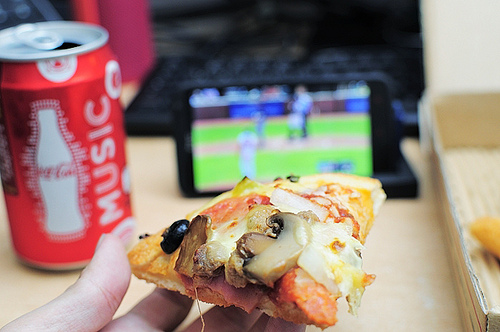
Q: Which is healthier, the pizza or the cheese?
A: The cheese is healthier than the pizza.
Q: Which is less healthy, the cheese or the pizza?
A: The pizza is less healthy than the cheese.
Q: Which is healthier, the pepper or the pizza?
A: The pepper is healthier than the pizza.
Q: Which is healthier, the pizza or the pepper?
A: The pepper is healthier than the pizza.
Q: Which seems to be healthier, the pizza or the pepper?
A: The pepper is healthier than the pizza.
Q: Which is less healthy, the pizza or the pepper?
A: The pizza is less healthy than the pepper.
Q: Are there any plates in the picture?
A: Yes, there is a plate.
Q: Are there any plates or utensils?
A: Yes, there is a plate.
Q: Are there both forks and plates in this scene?
A: No, there is a plate but no forks.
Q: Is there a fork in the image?
A: No, there are no forks.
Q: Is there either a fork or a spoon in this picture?
A: No, there are no forks or spoons.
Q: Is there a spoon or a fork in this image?
A: No, there are no forks or spoons.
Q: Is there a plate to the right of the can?
A: Yes, there is a plate to the right of the can.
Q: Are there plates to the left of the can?
A: No, the plate is to the right of the can.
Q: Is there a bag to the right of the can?
A: No, there is a plate to the right of the can.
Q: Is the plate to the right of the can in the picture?
A: Yes, the plate is to the right of the can.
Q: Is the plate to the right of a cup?
A: No, the plate is to the right of the can.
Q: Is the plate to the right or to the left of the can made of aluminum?
A: The plate is to the right of the can.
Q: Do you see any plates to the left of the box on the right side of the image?
A: Yes, there is a plate to the left of the box.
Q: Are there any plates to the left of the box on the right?
A: Yes, there is a plate to the left of the box.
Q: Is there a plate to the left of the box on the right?
A: Yes, there is a plate to the left of the box.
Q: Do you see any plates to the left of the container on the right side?
A: Yes, there is a plate to the left of the box.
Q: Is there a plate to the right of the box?
A: No, the plate is to the left of the box.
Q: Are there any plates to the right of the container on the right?
A: No, the plate is to the left of the box.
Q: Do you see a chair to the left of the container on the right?
A: No, there is a plate to the left of the box.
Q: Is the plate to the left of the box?
A: Yes, the plate is to the left of the box.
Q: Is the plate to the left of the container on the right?
A: Yes, the plate is to the left of the box.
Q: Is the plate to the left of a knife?
A: No, the plate is to the left of the box.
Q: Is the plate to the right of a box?
A: No, the plate is to the left of a box.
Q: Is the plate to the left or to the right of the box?
A: The plate is to the left of the box.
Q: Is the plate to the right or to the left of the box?
A: The plate is to the left of the box.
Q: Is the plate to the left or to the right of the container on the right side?
A: The plate is to the left of the box.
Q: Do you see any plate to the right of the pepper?
A: Yes, there is a plate to the right of the pepper.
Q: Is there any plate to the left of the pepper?
A: No, the plate is to the right of the pepper.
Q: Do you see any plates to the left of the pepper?
A: No, the plate is to the right of the pepper.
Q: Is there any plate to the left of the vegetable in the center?
A: No, the plate is to the right of the pepper.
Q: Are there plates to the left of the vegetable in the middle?
A: No, the plate is to the right of the pepper.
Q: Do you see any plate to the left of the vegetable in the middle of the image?
A: No, the plate is to the right of the pepper.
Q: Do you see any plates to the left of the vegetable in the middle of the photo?
A: No, the plate is to the right of the pepper.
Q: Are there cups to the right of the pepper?
A: No, there is a plate to the right of the pepper.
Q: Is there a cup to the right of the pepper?
A: No, there is a plate to the right of the pepper.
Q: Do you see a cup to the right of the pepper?
A: No, there is a plate to the right of the pepper.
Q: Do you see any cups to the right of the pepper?
A: No, there is a plate to the right of the pepper.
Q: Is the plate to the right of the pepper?
A: Yes, the plate is to the right of the pepper.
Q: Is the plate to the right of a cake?
A: No, the plate is to the right of the pepper.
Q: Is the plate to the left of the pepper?
A: No, the plate is to the right of the pepper.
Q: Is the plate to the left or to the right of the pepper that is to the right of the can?
A: The plate is to the right of the pepper.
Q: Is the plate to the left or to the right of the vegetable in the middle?
A: The plate is to the right of the pepper.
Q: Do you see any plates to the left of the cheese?
A: Yes, there is a plate to the left of the cheese.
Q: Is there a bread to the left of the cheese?
A: No, there is a plate to the left of the cheese.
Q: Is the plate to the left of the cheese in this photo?
A: Yes, the plate is to the left of the cheese.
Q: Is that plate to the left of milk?
A: No, the plate is to the left of the cheese.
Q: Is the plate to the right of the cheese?
A: No, the plate is to the left of the cheese.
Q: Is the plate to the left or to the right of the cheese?
A: The plate is to the left of the cheese.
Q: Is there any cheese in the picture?
A: Yes, there is cheese.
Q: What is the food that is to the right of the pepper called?
A: The food is cheese.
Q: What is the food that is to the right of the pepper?
A: The food is cheese.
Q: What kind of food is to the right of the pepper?
A: The food is cheese.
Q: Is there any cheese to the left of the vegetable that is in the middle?
A: No, the cheese is to the right of the pepper.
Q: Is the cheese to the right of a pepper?
A: Yes, the cheese is to the right of a pepper.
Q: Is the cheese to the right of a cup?
A: No, the cheese is to the right of a pepper.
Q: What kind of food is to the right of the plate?
A: The food is cheese.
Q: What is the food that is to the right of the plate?
A: The food is cheese.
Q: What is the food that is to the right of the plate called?
A: The food is cheese.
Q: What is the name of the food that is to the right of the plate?
A: The food is cheese.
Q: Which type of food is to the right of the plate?
A: The food is cheese.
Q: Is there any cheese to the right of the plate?
A: Yes, there is cheese to the right of the plate.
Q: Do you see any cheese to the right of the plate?
A: Yes, there is cheese to the right of the plate.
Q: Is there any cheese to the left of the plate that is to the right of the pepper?
A: No, the cheese is to the right of the plate.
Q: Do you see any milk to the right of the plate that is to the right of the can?
A: No, there is cheese to the right of the plate.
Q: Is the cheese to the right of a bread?
A: No, the cheese is to the right of the plate.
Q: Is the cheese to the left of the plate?
A: No, the cheese is to the right of the plate.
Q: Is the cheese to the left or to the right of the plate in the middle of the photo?
A: The cheese is to the right of the plate.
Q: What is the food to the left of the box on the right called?
A: The food is cheese.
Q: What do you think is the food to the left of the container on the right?
A: The food is cheese.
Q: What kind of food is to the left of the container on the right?
A: The food is cheese.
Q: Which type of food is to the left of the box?
A: The food is cheese.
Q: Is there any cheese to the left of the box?
A: Yes, there is cheese to the left of the box.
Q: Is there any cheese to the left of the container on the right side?
A: Yes, there is cheese to the left of the box.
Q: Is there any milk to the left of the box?
A: No, there is cheese to the left of the box.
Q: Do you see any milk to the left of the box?
A: No, there is cheese to the left of the box.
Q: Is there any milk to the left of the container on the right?
A: No, there is cheese to the left of the box.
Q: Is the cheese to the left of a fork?
A: No, the cheese is to the left of a box.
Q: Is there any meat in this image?
A: Yes, there is meat.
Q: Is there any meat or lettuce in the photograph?
A: Yes, there is meat.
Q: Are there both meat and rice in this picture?
A: No, there is meat but no rice.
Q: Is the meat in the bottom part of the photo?
A: Yes, the meat is in the bottom of the image.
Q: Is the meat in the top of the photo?
A: No, the meat is in the bottom of the image.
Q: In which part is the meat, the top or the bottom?
A: The meat is in the bottom of the image.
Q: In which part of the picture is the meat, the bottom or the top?
A: The meat is in the bottom of the image.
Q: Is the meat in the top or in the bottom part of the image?
A: The meat is in the bottom of the image.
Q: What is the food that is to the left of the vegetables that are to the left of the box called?
A: The food is meat.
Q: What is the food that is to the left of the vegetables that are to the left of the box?
A: The food is meat.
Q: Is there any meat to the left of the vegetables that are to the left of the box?
A: Yes, there is meat to the left of the veggies.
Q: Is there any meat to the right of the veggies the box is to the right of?
A: No, the meat is to the left of the vegetables.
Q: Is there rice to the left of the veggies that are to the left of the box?
A: No, there is meat to the left of the veggies.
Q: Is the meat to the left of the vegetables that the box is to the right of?
A: Yes, the meat is to the left of the veggies.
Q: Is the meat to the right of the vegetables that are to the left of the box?
A: No, the meat is to the left of the vegetables.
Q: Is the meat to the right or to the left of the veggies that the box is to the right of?
A: The meat is to the left of the vegetables.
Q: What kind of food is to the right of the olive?
A: The food is meat.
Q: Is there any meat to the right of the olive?
A: Yes, there is meat to the right of the olive.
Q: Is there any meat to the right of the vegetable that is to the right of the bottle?
A: Yes, there is meat to the right of the olive.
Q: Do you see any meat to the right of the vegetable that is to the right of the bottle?
A: Yes, there is meat to the right of the olive.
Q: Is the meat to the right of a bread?
A: No, the meat is to the right of the olive.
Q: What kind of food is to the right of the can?
A: The food is meat.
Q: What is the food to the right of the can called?
A: The food is meat.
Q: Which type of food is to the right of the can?
A: The food is meat.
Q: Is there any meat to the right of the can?
A: Yes, there is meat to the right of the can.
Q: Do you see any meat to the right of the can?
A: Yes, there is meat to the right of the can.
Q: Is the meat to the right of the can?
A: Yes, the meat is to the right of the can.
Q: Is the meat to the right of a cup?
A: No, the meat is to the right of the can.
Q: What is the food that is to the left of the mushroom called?
A: The food is meat.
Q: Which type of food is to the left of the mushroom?
A: The food is meat.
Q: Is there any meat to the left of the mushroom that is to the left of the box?
A: Yes, there is meat to the left of the mushroom.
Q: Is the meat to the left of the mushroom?
A: Yes, the meat is to the left of the mushroom.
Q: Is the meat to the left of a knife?
A: No, the meat is to the left of the mushroom.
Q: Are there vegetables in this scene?
A: Yes, there are vegetables.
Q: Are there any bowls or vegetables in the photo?
A: Yes, there are vegetables.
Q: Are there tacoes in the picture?
A: No, there are no tacoes.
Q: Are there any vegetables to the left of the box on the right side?
A: Yes, there are vegetables to the left of the box.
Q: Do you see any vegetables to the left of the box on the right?
A: Yes, there are vegetables to the left of the box.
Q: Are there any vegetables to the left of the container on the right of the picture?
A: Yes, there are vegetables to the left of the box.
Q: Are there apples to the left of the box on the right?
A: No, there are vegetables to the left of the box.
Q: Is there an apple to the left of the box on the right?
A: No, there are vegetables to the left of the box.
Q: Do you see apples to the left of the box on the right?
A: No, there are vegetables to the left of the box.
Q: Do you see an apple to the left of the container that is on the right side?
A: No, there are vegetables to the left of the box.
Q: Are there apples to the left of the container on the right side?
A: No, there are vegetables to the left of the box.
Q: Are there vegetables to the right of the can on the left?
A: Yes, there are vegetables to the right of the can.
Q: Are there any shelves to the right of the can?
A: No, there are vegetables to the right of the can.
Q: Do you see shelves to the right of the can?
A: No, there are vegetables to the right of the can.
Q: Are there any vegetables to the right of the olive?
A: Yes, there are vegetables to the right of the olive.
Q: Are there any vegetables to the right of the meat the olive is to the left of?
A: Yes, there are vegetables to the right of the meat.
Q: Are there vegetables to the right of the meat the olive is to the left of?
A: Yes, there are vegetables to the right of the meat.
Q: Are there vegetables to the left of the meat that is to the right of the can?
A: No, the vegetables are to the right of the meat.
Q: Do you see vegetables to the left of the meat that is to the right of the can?
A: No, the vegetables are to the right of the meat.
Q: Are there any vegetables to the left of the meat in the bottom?
A: No, the vegetables are to the right of the meat.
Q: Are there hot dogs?
A: No, there are no hot dogs.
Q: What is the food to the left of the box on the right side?
A: The food is a mushroom.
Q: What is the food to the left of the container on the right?
A: The food is a mushroom.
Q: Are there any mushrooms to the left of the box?
A: Yes, there is a mushroom to the left of the box.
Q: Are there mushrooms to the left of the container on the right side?
A: Yes, there is a mushroom to the left of the box.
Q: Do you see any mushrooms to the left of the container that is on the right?
A: Yes, there is a mushroom to the left of the box.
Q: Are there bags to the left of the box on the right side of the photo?
A: No, there is a mushroom to the left of the box.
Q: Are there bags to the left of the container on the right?
A: No, there is a mushroom to the left of the box.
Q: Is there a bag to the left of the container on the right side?
A: No, there is a mushroom to the left of the box.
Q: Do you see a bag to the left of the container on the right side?
A: No, there is a mushroom to the left of the box.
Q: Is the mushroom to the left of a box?
A: Yes, the mushroom is to the left of a box.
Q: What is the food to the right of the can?
A: The food is a mushroom.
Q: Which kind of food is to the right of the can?
A: The food is a mushroom.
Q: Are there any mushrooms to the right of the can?
A: Yes, there is a mushroom to the right of the can.